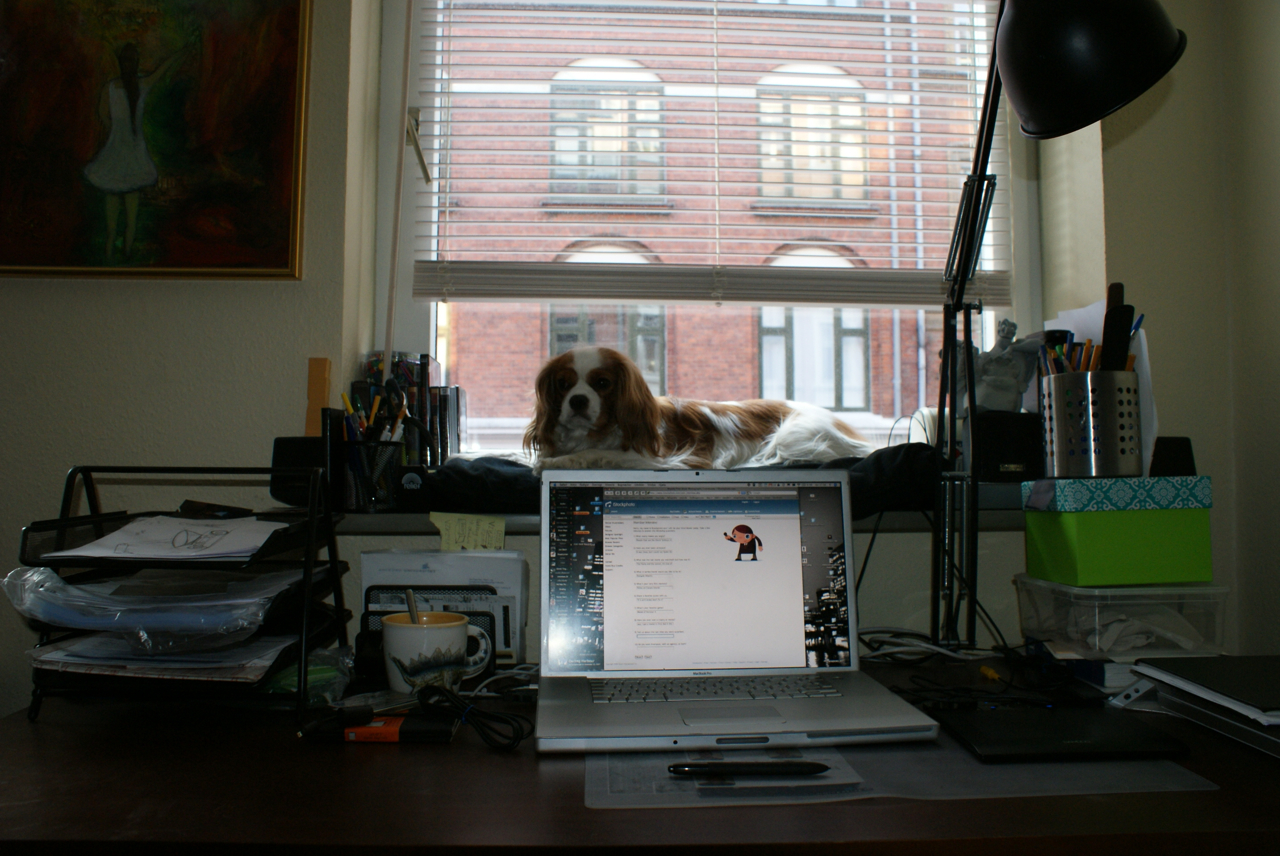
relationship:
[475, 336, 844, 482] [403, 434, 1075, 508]
dog sitting on windowsill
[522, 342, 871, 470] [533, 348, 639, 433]
dog has a head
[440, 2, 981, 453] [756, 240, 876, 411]
building has window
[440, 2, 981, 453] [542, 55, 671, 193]
building has window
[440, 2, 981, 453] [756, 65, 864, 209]
building has window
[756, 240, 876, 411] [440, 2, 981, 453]
window of building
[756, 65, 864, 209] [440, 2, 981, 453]
window of building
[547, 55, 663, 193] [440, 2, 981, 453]
window of building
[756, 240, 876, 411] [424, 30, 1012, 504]
window of building